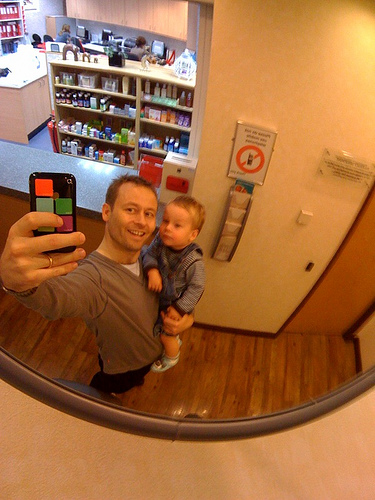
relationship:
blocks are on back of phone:
[34, 175, 74, 242] [26, 169, 80, 258]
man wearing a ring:
[1, 173, 198, 401] [46, 254, 56, 271]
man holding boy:
[1, 173, 198, 401] [142, 196, 205, 376]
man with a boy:
[1, 173, 198, 401] [142, 196, 205, 376]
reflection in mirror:
[2, 3, 375, 409] [1, 1, 375, 443]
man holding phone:
[1, 173, 198, 401] [26, 169, 80, 258]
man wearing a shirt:
[1, 173, 198, 401] [2, 249, 168, 373]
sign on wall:
[228, 121, 280, 186] [197, 0, 375, 337]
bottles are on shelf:
[56, 90, 90, 110] [42, 21, 197, 175]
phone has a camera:
[26, 169, 80, 258] [65, 178, 75, 186]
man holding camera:
[1, 173, 198, 401] [65, 178, 75, 186]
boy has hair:
[142, 196, 205, 376] [170, 196, 213, 232]